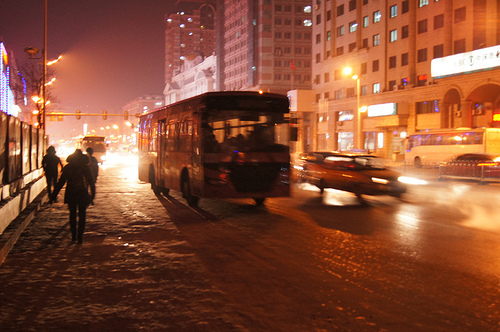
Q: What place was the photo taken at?
A: It was taken at the road.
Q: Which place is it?
A: It is a road.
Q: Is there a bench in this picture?
A: No, there are no benches.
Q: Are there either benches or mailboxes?
A: No, there are no benches or mailboxes.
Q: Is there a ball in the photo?
A: No, there are no balls.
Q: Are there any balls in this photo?
A: No, there are no balls.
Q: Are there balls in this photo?
A: No, there are no balls.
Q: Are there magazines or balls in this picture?
A: No, there are no balls or magazines.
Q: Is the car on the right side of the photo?
A: Yes, the car is on the right of the image.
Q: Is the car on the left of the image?
A: No, the car is on the right of the image.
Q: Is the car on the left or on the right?
A: The car is on the right of the image.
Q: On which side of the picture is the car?
A: The car is on the right of the image.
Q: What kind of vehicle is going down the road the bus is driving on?
A: The vehicle is a car.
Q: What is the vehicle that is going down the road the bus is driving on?
A: The vehicle is a car.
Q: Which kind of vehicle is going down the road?
A: The vehicle is a car.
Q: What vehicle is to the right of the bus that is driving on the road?
A: The vehicle is a car.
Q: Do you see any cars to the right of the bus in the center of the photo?
A: Yes, there is a car to the right of the bus.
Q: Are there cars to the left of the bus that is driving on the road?
A: No, the car is to the right of the bus.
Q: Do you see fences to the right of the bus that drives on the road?
A: No, there is a car to the right of the bus.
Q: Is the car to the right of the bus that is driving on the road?
A: Yes, the car is to the right of the bus.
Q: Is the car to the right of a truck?
A: No, the car is to the right of the bus.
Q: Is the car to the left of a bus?
A: No, the car is to the right of a bus.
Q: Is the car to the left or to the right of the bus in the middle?
A: The car is to the right of the bus.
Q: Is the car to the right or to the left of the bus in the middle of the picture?
A: The car is to the right of the bus.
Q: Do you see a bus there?
A: Yes, there is a bus.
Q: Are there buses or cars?
A: Yes, there is a bus.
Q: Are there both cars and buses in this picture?
A: Yes, there are both a bus and a car.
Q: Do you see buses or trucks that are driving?
A: Yes, the bus is driving.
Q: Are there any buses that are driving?
A: Yes, there is a bus that is driving.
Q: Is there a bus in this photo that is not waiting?
A: Yes, there is a bus that is driving.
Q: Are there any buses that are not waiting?
A: Yes, there is a bus that is driving.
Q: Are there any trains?
A: No, there are no trains.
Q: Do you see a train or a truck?
A: No, there are no trains or trucks.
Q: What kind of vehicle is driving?
A: The vehicle is a bus.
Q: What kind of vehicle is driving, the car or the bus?
A: The bus is driving.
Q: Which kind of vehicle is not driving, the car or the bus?
A: The car is not driving.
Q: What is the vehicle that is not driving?
A: The vehicle is a car.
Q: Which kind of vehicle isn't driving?
A: The vehicle is a car.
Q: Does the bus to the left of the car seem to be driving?
A: Yes, the bus is driving.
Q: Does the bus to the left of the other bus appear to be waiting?
A: No, the bus is driving.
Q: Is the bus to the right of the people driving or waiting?
A: The bus is driving.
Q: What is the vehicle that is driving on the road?
A: The vehicle is a bus.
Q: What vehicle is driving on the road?
A: The vehicle is a bus.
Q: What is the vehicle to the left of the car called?
A: The vehicle is a bus.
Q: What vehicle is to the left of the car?
A: The vehicle is a bus.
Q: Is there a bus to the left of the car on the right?
A: Yes, there is a bus to the left of the car.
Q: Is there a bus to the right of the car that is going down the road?
A: No, the bus is to the left of the car.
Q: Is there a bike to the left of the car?
A: No, there is a bus to the left of the car.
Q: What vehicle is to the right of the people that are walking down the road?
A: The vehicle is a bus.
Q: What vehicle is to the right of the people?
A: The vehicle is a bus.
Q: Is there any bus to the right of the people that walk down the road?
A: Yes, there is a bus to the right of the people.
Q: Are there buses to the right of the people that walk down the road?
A: Yes, there is a bus to the right of the people.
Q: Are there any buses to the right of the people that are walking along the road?
A: Yes, there is a bus to the right of the people.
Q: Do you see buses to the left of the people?
A: No, the bus is to the right of the people.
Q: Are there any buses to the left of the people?
A: No, the bus is to the right of the people.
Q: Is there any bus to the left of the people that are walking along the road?
A: No, the bus is to the right of the people.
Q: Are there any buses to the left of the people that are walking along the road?
A: No, the bus is to the right of the people.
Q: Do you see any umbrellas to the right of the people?
A: No, there is a bus to the right of the people.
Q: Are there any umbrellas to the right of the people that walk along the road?
A: No, there is a bus to the right of the people.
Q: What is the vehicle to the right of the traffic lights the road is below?
A: The vehicle is a bus.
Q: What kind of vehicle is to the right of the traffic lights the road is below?
A: The vehicle is a bus.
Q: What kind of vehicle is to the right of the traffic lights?
A: The vehicle is a bus.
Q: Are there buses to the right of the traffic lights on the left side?
A: Yes, there is a bus to the right of the traffic lights.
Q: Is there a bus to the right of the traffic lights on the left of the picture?
A: Yes, there is a bus to the right of the traffic lights.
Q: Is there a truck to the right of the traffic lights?
A: No, there is a bus to the right of the traffic lights.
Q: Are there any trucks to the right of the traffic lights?
A: No, there is a bus to the right of the traffic lights.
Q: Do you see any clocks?
A: No, there are no clocks.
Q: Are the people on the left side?
A: Yes, the people are on the left of the image.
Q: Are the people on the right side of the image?
A: No, the people are on the left of the image.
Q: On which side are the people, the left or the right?
A: The people are on the left of the image.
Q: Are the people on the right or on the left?
A: The people are on the left of the image.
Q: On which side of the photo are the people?
A: The people are on the left of the image.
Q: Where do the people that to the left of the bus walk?
A: The people walk on the road.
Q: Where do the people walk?
A: The people walk on the road.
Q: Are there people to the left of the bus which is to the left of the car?
A: Yes, there are people to the left of the bus.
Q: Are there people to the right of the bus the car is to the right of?
A: No, the people are to the left of the bus.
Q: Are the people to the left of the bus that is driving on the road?
A: Yes, the people are to the left of the bus.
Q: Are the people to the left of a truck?
A: No, the people are to the left of the bus.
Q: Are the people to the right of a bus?
A: No, the people are to the left of a bus.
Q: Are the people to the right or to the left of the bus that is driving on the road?
A: The people are to the left of the bus.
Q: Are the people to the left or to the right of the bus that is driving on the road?
A: The people are to the left of the bus.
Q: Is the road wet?
A: Yes, the road is wet.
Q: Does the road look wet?
A: Yes, the road is wet.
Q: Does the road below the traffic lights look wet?
A: Yes, the road is wet.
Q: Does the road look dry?
A: No, the road is wet.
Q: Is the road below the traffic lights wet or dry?
A: The road is wet.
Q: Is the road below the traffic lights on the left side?
A: Yes, the road is below the traffic lights.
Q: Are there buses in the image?
A: Yes, there is a bus.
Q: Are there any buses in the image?
A: Yes, there is a bus.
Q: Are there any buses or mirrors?
A: Yes, there is a bus.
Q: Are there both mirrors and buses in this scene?
A: No, there is a bus but no mirrors.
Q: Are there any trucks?
A: No, there are no trucks.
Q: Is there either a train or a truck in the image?
A: No, there are no trucks or trains.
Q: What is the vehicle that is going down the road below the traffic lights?
A: The vehicle is a bus.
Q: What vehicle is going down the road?
A: The vehicle is a bus.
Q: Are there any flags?
A: Yes, there is a flag.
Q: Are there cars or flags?
A: Yes, there is a flag.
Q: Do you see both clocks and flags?
A: No, there is a flag but no clocks.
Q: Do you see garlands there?
A: No, there are no garlands.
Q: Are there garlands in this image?
A: No, there are no garlands.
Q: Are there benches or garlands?
A: No, there are no garlands or benches.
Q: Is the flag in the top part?
A: Yes, the flag is in the top of the image.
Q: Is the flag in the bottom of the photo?
A: No, the flag is in the top of the image.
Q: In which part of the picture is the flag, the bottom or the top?
A: The flag is in the top of the image.